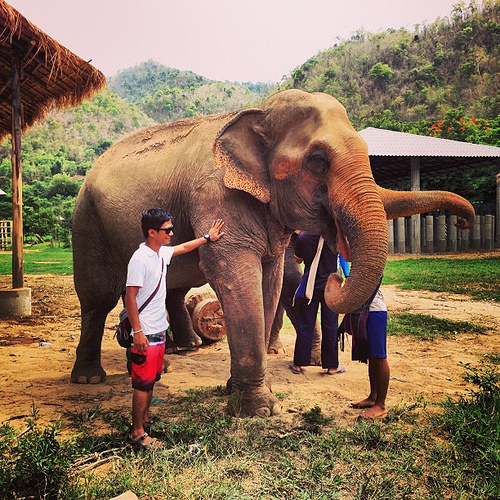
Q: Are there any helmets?
A: No, there are no helmets.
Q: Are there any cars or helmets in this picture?
A: No, there are no helmets or cars.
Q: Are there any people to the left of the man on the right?
A: Yes, there is a person to the left of the man.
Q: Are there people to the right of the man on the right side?
A: No, the person is to the left of the man.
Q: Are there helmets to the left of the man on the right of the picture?
A: No, there is a person to the left of the man.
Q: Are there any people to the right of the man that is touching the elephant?
A: Yes, there is a person to the right of the man.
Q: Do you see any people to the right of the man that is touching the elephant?
A: Yes, there is a person to the right of the man.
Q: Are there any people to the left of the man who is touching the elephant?
A: No, the person is to the right of the man.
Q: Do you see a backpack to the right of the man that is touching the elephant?
A: No, there is a person to the right of the man.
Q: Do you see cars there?
A: No, there are no cars.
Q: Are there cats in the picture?
A: No, there are no cats.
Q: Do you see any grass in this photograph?
A: Yes, there is grass.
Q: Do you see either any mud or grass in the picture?
A: Yes, there is grass.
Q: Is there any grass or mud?
A: Yes, there is grass.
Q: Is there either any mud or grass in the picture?
A: Yes, there is grass.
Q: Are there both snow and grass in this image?
A: No, there is grass but no snow.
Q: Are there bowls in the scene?
A: No, there are no bowls.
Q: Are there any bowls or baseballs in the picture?
A: No, there are no bowls or baseballs.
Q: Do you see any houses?
A: No, there are no houses.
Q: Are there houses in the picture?
A: No, there are no houses.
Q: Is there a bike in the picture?
A: No, there are no bikes.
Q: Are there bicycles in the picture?
A: No, there are no bicycles.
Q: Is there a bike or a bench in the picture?
A: No, there are no bikes or benches.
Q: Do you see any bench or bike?
A: No, there are no bikes or benches.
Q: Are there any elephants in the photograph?
A: Yes, there is an elephant.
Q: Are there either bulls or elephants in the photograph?
A: Yes, there is an elephant.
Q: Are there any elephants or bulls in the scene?
A: Yes, there is an elephant.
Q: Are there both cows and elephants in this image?
A: No, there is an elephant but no cows.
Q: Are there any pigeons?
A: No, there are no pigeons.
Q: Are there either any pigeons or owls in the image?
A: No, there are no pigeons or owls.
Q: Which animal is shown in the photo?
A: The animal is an elephant.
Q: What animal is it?
A: The animal is an elephant.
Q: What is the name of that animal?
A: This is an elephant.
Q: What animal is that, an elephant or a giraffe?
A: This is an elephant.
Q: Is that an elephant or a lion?
A: That is an elephant.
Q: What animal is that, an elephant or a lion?
A: That is an elephant.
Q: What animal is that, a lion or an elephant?
A: That is an elephant.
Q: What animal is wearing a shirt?
A: The animal is an elephant.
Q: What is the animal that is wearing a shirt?
A: The animal is an elephant.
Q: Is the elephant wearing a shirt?
A: Yes, the elephant is wearing a shirt.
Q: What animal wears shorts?
A: The elephant wears shorts.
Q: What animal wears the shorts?
A: The animal is an elephant.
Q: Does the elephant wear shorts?
A: Yes, the elephant wears shorts.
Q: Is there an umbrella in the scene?
A: No, there are no umbrellas.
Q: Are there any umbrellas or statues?
A: No, there are no umbrellas or statues.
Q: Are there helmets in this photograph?
A: No, there are no helmets.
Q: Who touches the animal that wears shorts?
A: The man touches the elephant.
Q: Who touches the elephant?
A: The man touches the elephant.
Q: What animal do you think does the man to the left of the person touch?
A: The man touches the elephant.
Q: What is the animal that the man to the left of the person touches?
A: The animal is an elephant.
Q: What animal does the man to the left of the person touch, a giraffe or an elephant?
A: The man touches an elephant.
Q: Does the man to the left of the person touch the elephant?
A: Yes, the man touches the elephant.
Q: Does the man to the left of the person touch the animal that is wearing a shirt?
A: Yes, the man touches the elephant.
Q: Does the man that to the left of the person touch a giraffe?
A: No, the man touches the elephant.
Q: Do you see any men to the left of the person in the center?
A: Yes, there is a man to the left of the person.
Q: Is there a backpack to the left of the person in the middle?
A: No, there is a man to the left of the person.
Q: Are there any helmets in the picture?
A: No, there are no helmets.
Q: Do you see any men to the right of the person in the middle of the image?
A: Yes, there is a man to the right of the person.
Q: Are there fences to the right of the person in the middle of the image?
A: No, there is a man to the right of the person.